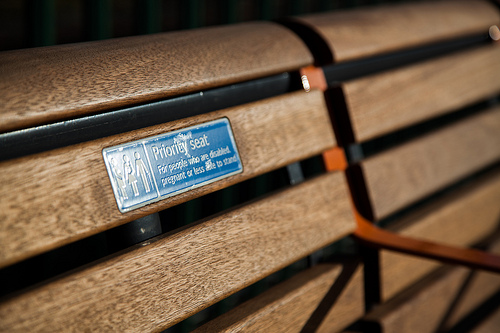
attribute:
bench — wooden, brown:
[1, 19, 372, 330]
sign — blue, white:
[96, 111, 246, 221]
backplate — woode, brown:
[0, 14, 312, 139]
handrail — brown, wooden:
[306, 66, 483, 286]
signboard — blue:
[96, 112, 245, 226]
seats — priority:
[11, 4, 483, 324]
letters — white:
[149, 122, 235, 191]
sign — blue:
[98, 117, 242, 206]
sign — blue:
[91, 118, 251, 203]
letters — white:
[150, 124, 238, 181]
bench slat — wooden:
[205, 199, 327, 276]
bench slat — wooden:
[7, 80, 356, 264]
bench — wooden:
[9, 21, 361, 314]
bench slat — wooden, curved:
[14, 36, 298, 77]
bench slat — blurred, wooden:
[352, 70, 482, 127]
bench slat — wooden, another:
[405, 197, 482, 271]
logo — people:
[110, 146, 162, 202]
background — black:
[6, 7, 297, 318]